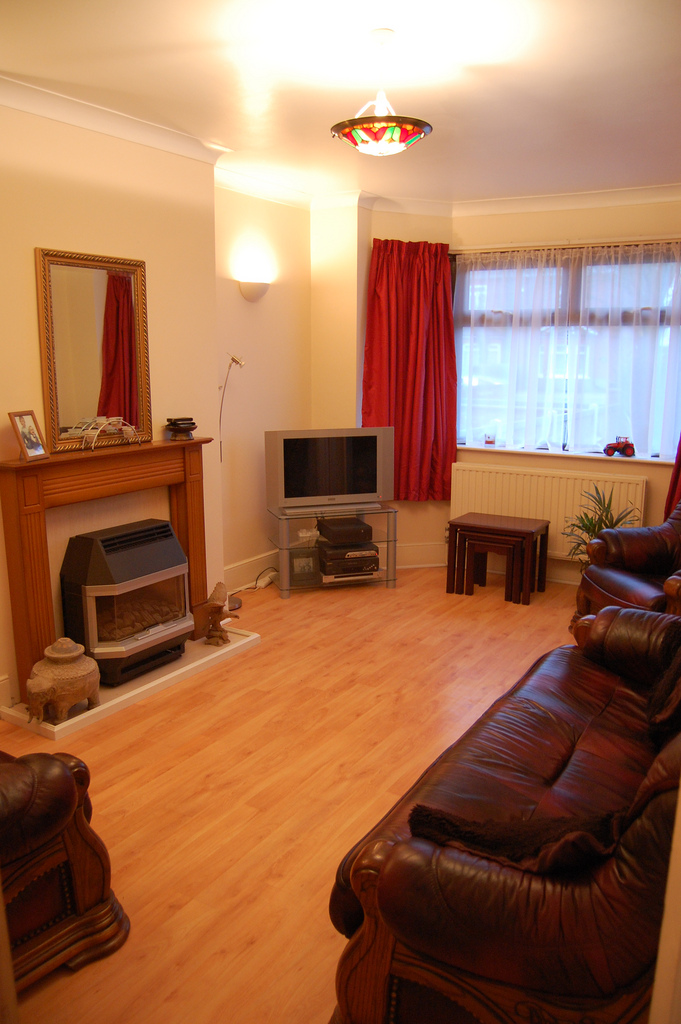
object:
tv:
[264, 427, 394, 517]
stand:
[267, 501, 399, 599]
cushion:
[586, 521, 675, 569]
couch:
[568, 495, 681, 635]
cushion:
[408, 803, 629, 874]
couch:
[327, 605, 681, 1024]